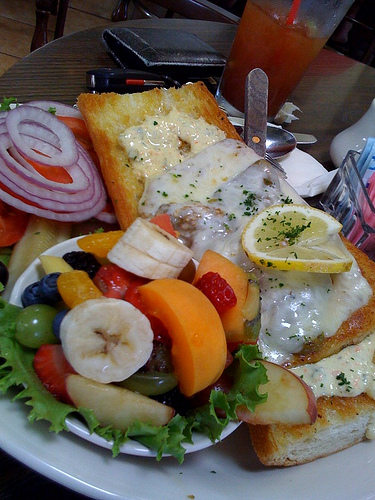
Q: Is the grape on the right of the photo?
A: No, the grape is on the left of the image.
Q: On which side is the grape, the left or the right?
A: The grape is on the left of the image.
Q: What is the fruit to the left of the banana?
A: The fruit is a grape.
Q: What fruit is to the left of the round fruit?
A: The fruit is a grape.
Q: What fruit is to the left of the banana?
A: The fruit is a grape.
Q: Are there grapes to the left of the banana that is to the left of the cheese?
A: Yes, there is a grape to the left of the banana.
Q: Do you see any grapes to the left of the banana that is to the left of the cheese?
A: Yes, there is a grape to the left of the banana.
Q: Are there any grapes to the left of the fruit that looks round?
A: Yes, there is a grape to the left of the banana.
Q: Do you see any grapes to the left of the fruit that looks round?
A: Yes, there is a grape to the left of the banana.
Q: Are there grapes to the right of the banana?
A: No, the grape is to the left of the banana.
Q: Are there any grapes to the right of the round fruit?
A: No, the grape is to the left of the banana.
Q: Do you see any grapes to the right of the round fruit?
A: No, the grape is to the left of the banana.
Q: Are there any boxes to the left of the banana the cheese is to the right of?
A: No, there is a grape to the left of the banana.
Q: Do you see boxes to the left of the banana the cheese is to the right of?
A: No, there is a grape to the left of the banana.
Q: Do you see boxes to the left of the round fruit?
A: No, there is a grape to the left of the banana.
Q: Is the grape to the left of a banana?
A: Yes, the grape is to the left of a banana.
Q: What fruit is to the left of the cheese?
A: The fruit is a grape.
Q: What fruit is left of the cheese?
A: The fruit is a grape.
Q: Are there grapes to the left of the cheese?
A: Yes, there is a grape to the left of the cheese.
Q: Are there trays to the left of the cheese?
A: No, there is a grape to the left of the cheese.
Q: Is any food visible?
A: Yes, there is food.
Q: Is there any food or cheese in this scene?
A: Yes, there is food.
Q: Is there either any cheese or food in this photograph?
A: Yes, there is food.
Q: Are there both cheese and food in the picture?
A: Yes, there are both food and cheese.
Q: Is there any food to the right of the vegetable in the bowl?
A: Yes, there is food to the right of the lettuce.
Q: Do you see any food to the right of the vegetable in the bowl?
A: Yes, there is food to the right of the lettuce.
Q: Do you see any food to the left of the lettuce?
A: No, the food is to the right of the lettuce.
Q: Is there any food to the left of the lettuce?
A: No, the food is to the right of the lettuce.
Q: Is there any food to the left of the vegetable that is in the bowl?
A: No, the food is to the right of the lettuce.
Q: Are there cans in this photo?
A: No, there are no cans.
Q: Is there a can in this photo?
A: No, there are no cans.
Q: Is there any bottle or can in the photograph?
A: No, there are no cans or bottles.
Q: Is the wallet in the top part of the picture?
A: Yes, the wallet is in the top of the image.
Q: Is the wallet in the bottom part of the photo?
A: No, the wallet is in the top of the image.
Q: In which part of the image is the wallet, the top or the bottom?
A: The wallet is in the top of the image.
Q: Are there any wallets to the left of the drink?
A: Yes, there is a wallet to the left of the drink.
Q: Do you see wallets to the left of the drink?
A: Yes, there is a wallet to the left of the drink.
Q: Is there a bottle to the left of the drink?
A: No, there is a wallet to the left of the drink.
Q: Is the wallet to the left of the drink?
A: Yes, the wallet is to the left of the drink.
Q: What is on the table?
A: The wallet is on the table.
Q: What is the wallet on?
A: The wallet is on the table.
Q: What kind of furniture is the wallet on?
A: The wallet is on the table.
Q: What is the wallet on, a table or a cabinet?
A: The wallet is on a table.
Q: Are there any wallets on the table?
A: Yes, there is a wallet on the table.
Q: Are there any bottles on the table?
A: No, there is a wallet on the table.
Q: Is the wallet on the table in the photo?
A: Yes, the wallet is on the table.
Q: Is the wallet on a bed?
A: No, the wallet is on the table.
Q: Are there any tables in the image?
A: Yes, there is a table.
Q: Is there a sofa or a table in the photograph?
A: Yes, there is a table.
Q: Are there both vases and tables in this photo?
A: No, there is a table but no vases.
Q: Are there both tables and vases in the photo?
A: No, there is a table but no vases.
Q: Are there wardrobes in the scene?
A: No, there are no wardrobes.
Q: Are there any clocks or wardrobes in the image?
A: No, there are no wardrobes or clocks.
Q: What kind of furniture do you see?
A: The furniture is a table.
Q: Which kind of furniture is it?
A: The piece of furniture is a table.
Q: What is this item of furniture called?
A: This is a table.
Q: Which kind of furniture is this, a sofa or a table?
A: This is a table.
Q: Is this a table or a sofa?
A: This is a table.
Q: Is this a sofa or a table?
A: This is a table.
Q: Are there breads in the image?
A: Yes, there is a bread.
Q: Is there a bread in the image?
A: Yes, there is a bread.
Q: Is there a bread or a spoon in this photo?
A: Yes, there is a bread.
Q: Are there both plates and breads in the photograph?
A: Yes, there are both a bread and a plate.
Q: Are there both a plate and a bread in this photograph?
A: Yes, there are both a bread and a plate.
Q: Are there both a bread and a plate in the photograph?
A: Yes, there are both a bread and a plate.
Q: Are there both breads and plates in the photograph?
A: Yes, there are both a bread and a plate.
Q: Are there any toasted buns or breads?
A: Yes, there is a toasted bread.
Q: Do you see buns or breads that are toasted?
A: Yes, the bread is toasted.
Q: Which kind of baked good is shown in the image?
A: The baked good is a bread.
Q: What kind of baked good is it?
A: The food is a bread.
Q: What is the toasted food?
A: The food is a bread.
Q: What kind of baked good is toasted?
A: The baked good is a bread.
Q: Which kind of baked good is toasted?
A: The baked good is a bread.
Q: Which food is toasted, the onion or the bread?
A: The bread is toasted.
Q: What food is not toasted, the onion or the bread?
A: The onion is not toasted.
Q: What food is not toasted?
A: The food is an onion.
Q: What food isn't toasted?
A: The food is an onion.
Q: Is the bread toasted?
A: Yes, the bread is toasted.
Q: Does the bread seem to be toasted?
A: Yes, the bread is toasted.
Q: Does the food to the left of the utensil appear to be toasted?
A: Yes, the bread is toasted.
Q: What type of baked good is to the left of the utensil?
A: The food is a bread.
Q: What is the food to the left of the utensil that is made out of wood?
A: The food is a bread.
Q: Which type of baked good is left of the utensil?
A: The food is a bread.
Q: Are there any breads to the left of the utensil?
A: Yes, there is a bread to the left of the utensil.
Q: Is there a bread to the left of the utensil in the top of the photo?
A: Yes, there is a bread to the left of the utensil.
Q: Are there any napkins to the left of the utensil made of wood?
A: No, there is a bread to the left of the utensil.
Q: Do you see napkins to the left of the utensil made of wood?
A: No, there is a bread to the left of the utensil.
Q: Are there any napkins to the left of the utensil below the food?
A: No, there is a bread to the left of the utensil.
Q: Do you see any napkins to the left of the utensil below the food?
A: No, there is a bread to the left of the utensil.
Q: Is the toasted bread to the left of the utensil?
A: Yes, the bread is to the left of the utensil.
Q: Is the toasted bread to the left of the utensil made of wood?
A: Yes, the bread is to the left of the utensil.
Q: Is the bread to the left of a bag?
A: No, the bread is to the left of the utensil.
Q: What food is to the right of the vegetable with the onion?
A: The food is a bread.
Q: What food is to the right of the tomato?
A: The food is a bread.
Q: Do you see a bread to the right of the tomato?
A: Yes, there is a bread to the right of the tomato.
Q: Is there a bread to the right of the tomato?
A: Yes, there is a bread to the right of the tomato.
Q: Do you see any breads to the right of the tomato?
A: Yes, there is a bread to the right of the tomato.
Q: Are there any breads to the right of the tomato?
A: Yes, there is a bread to the right of the tomato.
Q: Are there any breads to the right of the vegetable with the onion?
A: Yes, there is a bread to the right of the tomato.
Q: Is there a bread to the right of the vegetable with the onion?
A: Yes, there is a bread to the right of the tomato.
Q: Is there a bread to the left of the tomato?
A: No, the bread is to the right of the tomato.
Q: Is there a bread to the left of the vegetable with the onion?
A: No, the bread is to the right of the tomato.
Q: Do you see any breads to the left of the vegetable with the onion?
A: No, the bread is to the right of the tomato.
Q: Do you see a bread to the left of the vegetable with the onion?
A: No, the bread is to the right of the tomato.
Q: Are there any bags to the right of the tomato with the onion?
A: No, there is a bread to the right of the tomato.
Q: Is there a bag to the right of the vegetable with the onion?
A: No, there is a bread to the right of the tomato.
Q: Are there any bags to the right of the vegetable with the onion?
A: No, there is a bread to the right of the tomato.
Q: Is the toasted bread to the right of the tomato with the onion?
A: Yes, the bread is to the right of the tomato.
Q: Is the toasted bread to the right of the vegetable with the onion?
A: Yes, the bread is to the right of the tomato.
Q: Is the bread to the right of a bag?
A: No, the bread is to the right of the tomato.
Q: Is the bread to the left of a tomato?
A: No, the bread is to the right of a tomato.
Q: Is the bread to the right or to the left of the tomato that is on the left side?
A: The bread is to the right of the tomato.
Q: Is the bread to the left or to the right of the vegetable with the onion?
A: The bread is to the right of the tomato.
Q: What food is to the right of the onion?
A: The food is a bread.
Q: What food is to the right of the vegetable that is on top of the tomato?
A: The food is a bread.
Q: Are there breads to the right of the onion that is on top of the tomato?
A: Yes, there is a bread to the right of the onion.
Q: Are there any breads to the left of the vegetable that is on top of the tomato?
A: No, the bread is to the right of the onion.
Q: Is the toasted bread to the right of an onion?
A: Yes, the bread is to the right of an onion.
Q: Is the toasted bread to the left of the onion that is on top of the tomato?
A: No, the bread is to the right of the onion.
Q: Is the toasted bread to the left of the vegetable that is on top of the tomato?
A: No, the bread is to the right of the onion.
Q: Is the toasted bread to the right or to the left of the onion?
A: The bread is to the right of the onion.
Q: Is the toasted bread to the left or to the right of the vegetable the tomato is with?
A: The bread is to the right of the onion.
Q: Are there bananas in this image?
A: Yes, there is a banana.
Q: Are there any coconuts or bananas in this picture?
A: Yes, there is a banana.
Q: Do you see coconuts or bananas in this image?
A: Yes, there is a banana.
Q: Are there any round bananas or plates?
A: Yes, there is a round banana.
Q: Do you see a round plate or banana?
A: Yes, there is a round banana.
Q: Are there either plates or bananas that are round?
A: Yes, the banana is round.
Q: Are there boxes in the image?
A: No, there are no boxes.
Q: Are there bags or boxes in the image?
A: No, there are no boxes or bags.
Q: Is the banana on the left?
A: Yes, the banana is on the left of the image.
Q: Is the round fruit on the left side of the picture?
A: Yes, the banana is on the left of the image.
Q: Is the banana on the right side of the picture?
A: No, the banana is on the left of the image.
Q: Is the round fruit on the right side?
A: No, the banana is on the left of the image.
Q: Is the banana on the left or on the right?
A: The banana is on the left of the image.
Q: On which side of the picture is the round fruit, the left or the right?
A: The banana is on the left of the image.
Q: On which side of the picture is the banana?
A: The banana is on the left of the image.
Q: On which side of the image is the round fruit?
A: The banana is on the left of the image.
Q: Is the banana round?
A: Yes, the banana is round.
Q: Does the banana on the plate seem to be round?
A: Yes, the banana is round.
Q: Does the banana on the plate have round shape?
A: Yes, the banana is round.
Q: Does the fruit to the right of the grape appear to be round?
A: Yes, the banana is round.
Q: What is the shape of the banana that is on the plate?
A: The banana is round.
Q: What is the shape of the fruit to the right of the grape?
A: The banana is round.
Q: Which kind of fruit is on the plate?
A: The fruit is a banana.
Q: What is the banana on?
A: The banana is on the plate.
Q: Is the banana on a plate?
A: Yes, the banana is on a plate.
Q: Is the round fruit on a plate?
A: Yes, the banana is on a plate.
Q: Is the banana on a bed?
A: No, the banana is on a plate.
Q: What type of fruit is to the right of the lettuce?
A: The fruit is a banana.